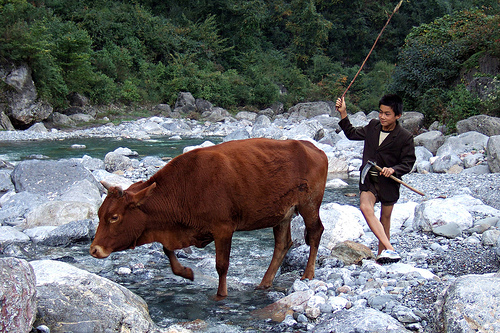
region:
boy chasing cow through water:
[76, 86, 422, 261]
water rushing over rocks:
[3, 122, 356, 214]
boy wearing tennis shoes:
[328, 77, 428, 267]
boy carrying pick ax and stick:
[328, 63, 419, 265]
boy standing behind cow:
[67, 85, 417, 265]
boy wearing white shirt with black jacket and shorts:
[343, 27, 414, 264]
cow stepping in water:
[76, 129, 356, 291]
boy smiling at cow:
[60, 83, 418, 288]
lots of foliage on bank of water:
[0, 0, 499, 140]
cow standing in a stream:
[94, 132, 340, 318]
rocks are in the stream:
[53, 171, 497, 319]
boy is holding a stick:
[353, 19, 453, 220]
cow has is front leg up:
[25, 145, 389, 302]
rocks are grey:
[38, 256, 499, 323]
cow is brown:
[71, 155, 333, 291]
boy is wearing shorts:
[355, 177, 413, 241]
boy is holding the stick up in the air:
[335, 10, 428, 159]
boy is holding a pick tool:
[361, 157, 452, 185]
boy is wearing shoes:
[353, 231, 439, 285]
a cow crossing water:
[54, 67, 423, 325]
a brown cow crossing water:
[61, 37, 401, 298]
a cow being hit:
[87, 7, 448, 330]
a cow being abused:
[36, 3, 408, 331]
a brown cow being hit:
[55, 12, 482, 305]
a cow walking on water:
[79, 40, 436, 294]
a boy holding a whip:
[302, 24, 471, 270]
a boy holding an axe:
[314, 42, 463, 278]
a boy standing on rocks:
[309, 52, 457, 248]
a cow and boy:
[57, 13, 410, 331]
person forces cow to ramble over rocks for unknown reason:
[330, 78, 425, 278]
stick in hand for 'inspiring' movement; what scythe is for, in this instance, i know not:
[330, 0, 410, 110]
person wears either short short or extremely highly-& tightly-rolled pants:
[357, 186, 404, 266]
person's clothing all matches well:
[335, 110, 420, 208]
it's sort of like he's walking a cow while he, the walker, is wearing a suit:
[330, 87, 427, 270]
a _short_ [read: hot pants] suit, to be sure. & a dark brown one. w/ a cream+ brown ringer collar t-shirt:
[335, 108, 420, 210]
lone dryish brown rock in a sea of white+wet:
[322, 233, 377, 273]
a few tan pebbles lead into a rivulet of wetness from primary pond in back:
[177, 276, 357, 331]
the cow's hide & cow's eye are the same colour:
[102, 210, 127, 225]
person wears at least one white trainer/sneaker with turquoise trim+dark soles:
[370, 248, 405, 265]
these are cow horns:
[89, 168, 160, 216]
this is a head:
[78, 183, 157, 258]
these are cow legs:
[171, 216, 327, 295]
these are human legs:
[349, 184, 406, 264]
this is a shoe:
[366, 239, 411, 266]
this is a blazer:
[331, 120, 436, 202]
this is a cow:
[51, 133, 351, 317]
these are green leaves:
[156, 36, 202, 68]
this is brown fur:
[193, 167, 230, 199]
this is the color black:
[394, 132, 409, 150]